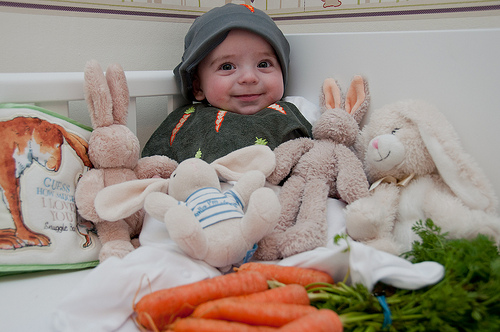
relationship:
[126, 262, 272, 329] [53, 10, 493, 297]
carrot sitting on bed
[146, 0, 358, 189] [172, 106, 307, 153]
baby wearing costume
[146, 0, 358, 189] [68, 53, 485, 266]
baby and rabbits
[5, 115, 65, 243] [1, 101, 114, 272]
bunny on blanket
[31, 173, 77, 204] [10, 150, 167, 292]
letters on blanke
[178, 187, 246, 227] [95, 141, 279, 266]
white shirt on bunny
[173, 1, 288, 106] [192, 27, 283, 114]
grey hat on head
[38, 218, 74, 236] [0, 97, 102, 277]
letters on blanket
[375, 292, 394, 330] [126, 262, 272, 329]
rubber bands on carrot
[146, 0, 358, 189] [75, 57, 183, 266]
baby has animal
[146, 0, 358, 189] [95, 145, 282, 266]
baby has animal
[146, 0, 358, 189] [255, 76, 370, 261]
baby has animal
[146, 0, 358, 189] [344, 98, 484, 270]
baby has animal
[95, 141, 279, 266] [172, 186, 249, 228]
bunny wearing shirt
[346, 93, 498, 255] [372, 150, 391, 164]
stuffed bunny has smile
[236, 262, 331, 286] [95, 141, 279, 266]
carrot for bunny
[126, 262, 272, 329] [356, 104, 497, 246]
carrot for bunny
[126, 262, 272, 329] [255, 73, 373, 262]
carrot for bunny rabbit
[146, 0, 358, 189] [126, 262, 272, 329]
baby wearing carrot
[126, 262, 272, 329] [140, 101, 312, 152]
carrot on clothing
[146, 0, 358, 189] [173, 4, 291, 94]
baby wearing cap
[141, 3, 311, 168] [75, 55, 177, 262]
kid laying with stuffed animal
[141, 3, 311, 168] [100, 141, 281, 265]
kid laying with stuffed animal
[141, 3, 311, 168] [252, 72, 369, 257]
kid laying with stuffed animal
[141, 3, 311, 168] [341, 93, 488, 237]
kid laying with stuffed animal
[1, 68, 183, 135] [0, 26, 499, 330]
headboard on bed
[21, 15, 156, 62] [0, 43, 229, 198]
wall behind bed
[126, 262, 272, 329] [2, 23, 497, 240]
carrot on bed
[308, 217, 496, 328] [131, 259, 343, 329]
leaves on carrots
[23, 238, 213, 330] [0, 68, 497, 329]
blankets on bed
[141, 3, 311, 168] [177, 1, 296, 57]
kid with hat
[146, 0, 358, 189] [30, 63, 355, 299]
baby on bed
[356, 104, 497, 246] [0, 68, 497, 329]
bunny on bed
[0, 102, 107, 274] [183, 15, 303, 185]
bib on baby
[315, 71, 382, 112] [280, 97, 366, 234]
ears of stuffed rabbit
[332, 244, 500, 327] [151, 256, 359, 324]
tops of carrots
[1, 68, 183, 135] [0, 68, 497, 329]
headboard of bed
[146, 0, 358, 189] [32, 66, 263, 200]
baby in crib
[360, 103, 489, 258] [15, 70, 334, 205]
rabbit in crib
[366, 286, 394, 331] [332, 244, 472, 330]
tie around tops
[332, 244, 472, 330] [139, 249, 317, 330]
tops on carrot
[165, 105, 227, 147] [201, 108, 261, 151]
carrots on bib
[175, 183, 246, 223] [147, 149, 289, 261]
shirt on stuffed animal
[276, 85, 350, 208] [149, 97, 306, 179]
rabbit on white bib